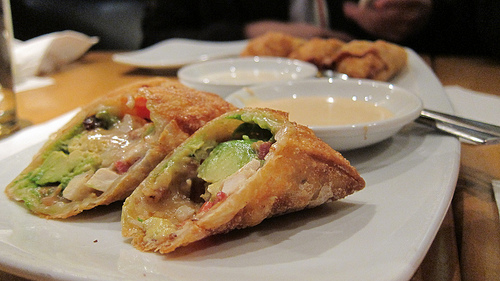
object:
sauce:
[313, 98, 352, 122]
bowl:
[224, 79, 425, 149]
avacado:
[202, 136, 253, 179]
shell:
[106, 107, 366, 252]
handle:
[416, 109, 500, 147]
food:
[118, 104, 361, 254]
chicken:
[95, 134, 153, 168]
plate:
[344, 206, 431, 276]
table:
[0, 48, 149, 141]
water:
[0, 55, 17, 126]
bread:
[334, 40, 406, 79]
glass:
[1, 36, 22, 134]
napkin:
[4, 31, 98, 89]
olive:
[237, 123, 269, 141]